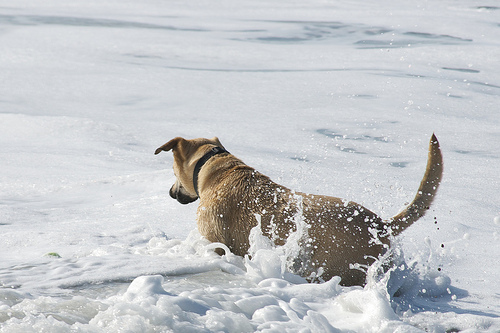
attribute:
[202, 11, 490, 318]
snow — moving, frozen, pristine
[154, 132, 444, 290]
dog — jumping, brown, medium sized, playing, big, yellow, fetching, wading, splashing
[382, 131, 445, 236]
brown tail — stands at attention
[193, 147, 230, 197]
black collar — nylon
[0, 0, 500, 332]
snow — flat, white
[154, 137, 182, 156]
ear — floppy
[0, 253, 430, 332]
water — splashing, calm, blue, foaming, swirling, rippling